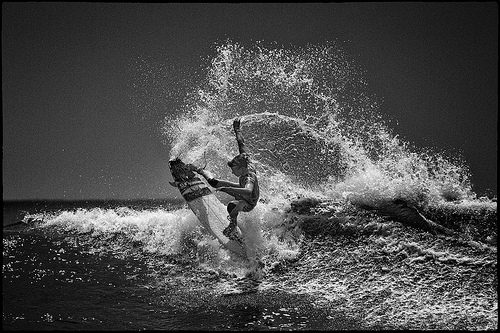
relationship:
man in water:
[216, 138, 266, 236] [42, 226, 186, 327]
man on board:
[216, 138, 266, 236] [167, 151, 230, 250]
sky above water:
[47, 12, 161, 80] [42, 226, 186, 327]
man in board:
[216, 138, 266, 236] [167, 151, 230, 250]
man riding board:
[216, 138, 266, 236] [167, 151, 230, 250]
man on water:
[216, 138, 266, 236] [42, 226, 186, 327]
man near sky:
[216, 138, 266, 236] [47, 12, 161, 80]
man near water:
[216, 138, 266, 236] [42, 226, 186, 327]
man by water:
[216, 138, 266, 236] [42, 226, 186, 327]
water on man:
[42, 226, 186, 327] [216, 138, 266, 236]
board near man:
[167, 151, 230, 250] [216, 138, 266, 236]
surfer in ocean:
[186, 117, 260, 237] [3, 199, 497, 330]